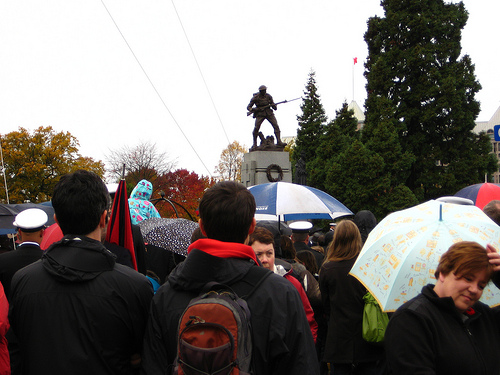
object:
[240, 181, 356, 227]
umbrella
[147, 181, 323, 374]
man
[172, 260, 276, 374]
backpack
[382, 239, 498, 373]
lady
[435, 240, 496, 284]
hair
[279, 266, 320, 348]
sweater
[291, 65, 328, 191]
tree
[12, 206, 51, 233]
hat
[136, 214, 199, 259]
umbrella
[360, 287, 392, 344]
bag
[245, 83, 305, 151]
statue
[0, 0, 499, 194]
sky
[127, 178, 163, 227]
kid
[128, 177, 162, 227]
raincoat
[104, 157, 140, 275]
umbrella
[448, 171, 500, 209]
umbrella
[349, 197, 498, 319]
umbrella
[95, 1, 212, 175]
wire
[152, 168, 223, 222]
tree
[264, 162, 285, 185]
circle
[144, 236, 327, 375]
jacket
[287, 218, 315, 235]
cap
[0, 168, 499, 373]
crowd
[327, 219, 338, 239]
person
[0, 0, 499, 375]
photo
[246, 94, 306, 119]
gun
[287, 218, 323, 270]
member